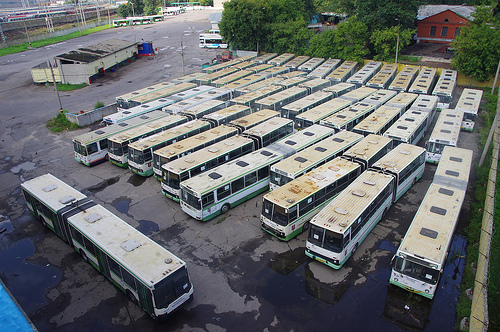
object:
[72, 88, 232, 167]
bus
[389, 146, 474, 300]
bus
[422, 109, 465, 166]
bus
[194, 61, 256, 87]
bus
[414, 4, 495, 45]
building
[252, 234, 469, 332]
puddle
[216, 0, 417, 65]
trees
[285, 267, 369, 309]
ground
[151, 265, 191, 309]
windshield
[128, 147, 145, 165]
windshield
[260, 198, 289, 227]
windshield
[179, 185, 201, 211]
windshield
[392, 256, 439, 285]
windshield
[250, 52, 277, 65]
bus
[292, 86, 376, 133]
bus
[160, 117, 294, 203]
bus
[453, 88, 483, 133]
buses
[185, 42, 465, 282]
picture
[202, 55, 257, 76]
bus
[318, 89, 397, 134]
bus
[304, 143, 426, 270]
bus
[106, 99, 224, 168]
bus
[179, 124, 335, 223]
bus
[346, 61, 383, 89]
buses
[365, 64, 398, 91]
buses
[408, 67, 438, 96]
buses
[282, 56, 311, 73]
buses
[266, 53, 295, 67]
buses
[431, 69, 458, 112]
buses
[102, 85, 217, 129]
bus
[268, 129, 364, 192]
bus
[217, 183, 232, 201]
windows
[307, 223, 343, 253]
windows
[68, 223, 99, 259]
windows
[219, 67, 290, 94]
bus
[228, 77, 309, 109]
bus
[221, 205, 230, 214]
wheel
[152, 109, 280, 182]
bus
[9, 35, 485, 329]
parking lot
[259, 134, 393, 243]
bus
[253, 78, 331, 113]
bus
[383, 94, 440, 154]
bus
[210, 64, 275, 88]
bus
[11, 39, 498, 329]
lot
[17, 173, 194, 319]
bus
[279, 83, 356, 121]
bus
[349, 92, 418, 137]
bus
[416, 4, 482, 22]
top